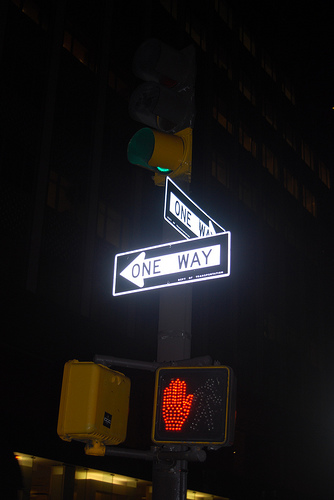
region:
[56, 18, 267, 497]
Street signs on a pole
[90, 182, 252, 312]
Lighted one way signs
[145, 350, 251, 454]
a cross walk sign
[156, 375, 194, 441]
An orange hand sign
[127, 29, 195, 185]
A stop light lit green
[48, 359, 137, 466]
The back of a cross walk sign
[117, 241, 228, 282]
A sign that says One Way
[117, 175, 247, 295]
Two signs that say One Way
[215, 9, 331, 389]
A building behind the sign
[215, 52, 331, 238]
Lights on in the windows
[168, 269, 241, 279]
small writing on black sign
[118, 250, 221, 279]
white arrow on sign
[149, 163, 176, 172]
section of green light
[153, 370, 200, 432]
orange hand on traffic signal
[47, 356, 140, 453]
yellow traffic light box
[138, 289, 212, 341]
thick black post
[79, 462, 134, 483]
lights in building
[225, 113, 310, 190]
windows in tall building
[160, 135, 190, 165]
yellow color on side of traffic signal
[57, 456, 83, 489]
black frame on building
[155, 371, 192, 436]
a hand lighting up red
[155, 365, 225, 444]
a crosswalk sign that is saying it is not safe to cross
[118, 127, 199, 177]
a green light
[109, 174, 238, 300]
one way signs glowing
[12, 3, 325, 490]
night time outside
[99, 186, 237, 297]
the sign is black and white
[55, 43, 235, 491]
a light pole in use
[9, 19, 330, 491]
A building near the light pole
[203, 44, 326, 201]
windows on the building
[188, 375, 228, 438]
a walking person sign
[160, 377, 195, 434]
a red hand signal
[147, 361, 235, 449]
a pedestrian light bank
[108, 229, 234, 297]
a black and white sign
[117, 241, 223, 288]
a white arrow on the sign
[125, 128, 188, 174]
a green traffic light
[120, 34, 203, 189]
a traffic light bank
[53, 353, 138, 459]
a yellow light back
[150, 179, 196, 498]
a black metal pole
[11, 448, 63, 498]
a window on the building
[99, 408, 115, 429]
a sticker on the lights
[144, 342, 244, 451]
Pedestrian crossing sign on pole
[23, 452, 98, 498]
Lights on the building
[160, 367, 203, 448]
Red hand on the sign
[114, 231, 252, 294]
One way sign on the pole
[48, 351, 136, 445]
Yellow sign on the pole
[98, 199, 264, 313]
the signs light up from headlights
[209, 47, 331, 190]
Tall building with windows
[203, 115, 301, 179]
Light showing through the windows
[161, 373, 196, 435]
The hand is red and lit up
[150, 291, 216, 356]
The pole is made of metal